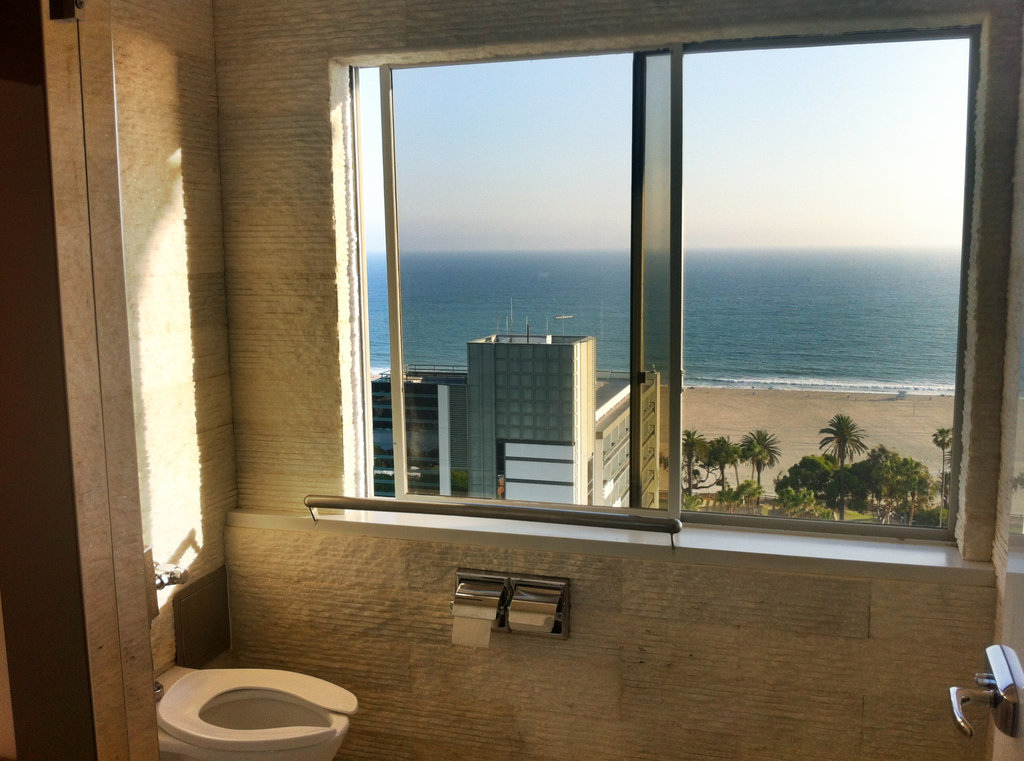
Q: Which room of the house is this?
A: It is a bathroom.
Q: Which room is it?
A: It is a bathroom.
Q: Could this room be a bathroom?
A: Yes, it is a bathroom.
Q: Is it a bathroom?
A: Yes, it is a bathroom.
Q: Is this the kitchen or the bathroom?
A: It is the bathroom.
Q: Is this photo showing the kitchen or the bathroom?
A: It is showing the bathroom.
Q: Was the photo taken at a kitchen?
A: No, the picture was taken in a bathroom.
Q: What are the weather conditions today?
A: It is cloudless.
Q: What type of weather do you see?
A: It is cloudless.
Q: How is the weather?
A: It is cloudless.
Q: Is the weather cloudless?
A: Yes, it is cloudless.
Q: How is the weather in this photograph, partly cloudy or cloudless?
A: It is cloudless.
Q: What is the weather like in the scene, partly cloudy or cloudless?
A: It is cloudless.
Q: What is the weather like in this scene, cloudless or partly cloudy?
A: It is cloudless.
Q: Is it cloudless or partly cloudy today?
A: It is cloudless.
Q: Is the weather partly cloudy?
A: No, it is cloudless.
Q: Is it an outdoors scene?
A: Yes, it is outdoors.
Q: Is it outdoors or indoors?
A: It is outdoors.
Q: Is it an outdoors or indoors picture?
A: It is outdoors.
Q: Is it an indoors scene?
A: No, it is outdoors.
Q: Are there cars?
A: No, there are no cars.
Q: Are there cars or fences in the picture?
A: No, there are no cars or fences.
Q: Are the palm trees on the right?
A: Yes, the palm trees are on the right of the image.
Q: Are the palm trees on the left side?
A: No, the palm trees are on the right of the image.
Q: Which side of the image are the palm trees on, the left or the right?
A: The palm trees are on the right of the image.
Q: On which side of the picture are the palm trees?
A: The palm trees are on the right of the image.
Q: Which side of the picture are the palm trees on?
A: The palm trees are on the right of the image.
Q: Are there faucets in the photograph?
A: No, there are no faucets.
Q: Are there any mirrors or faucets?
A: No, there are no faucets or mirrors.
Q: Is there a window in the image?
A: Yes, there is a window.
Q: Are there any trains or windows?
A: Yes, there is a window.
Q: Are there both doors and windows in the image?
A: Yes, there are both a window and a door.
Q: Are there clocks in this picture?
A: No, there are no clocks.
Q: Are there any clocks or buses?
A: No, there are no clocks or buses.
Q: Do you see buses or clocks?
A: No, there are no clocks or buses.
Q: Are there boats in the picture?
A: No, there are no boats.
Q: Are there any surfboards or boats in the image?
A: No, there are no boats or surfboards.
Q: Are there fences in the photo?
A: No, there are no fences.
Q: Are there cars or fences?
A: No, there are no fences or cars.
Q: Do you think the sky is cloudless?
A: Yes, the sky is cloudless.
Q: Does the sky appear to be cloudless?
A: Yes, the sky is cloudless.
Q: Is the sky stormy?
A: No, the sky is cloudless.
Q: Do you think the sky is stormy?
A: No, the sky is cloudless.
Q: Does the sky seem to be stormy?
A: No, the sky is cloudless.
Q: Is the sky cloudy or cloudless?
A: The sky is cloudless.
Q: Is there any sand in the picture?
A: Yes, there is sand.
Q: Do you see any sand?
A: Yes, there is sand.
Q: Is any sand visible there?
A: Yes, there is sand.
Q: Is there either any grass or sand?
A: Yes, there is sand.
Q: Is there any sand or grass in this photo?
A: Yes, there is sand.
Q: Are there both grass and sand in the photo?
A: No, there is sand but no grass.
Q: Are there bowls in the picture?
A: No, there are no bowls.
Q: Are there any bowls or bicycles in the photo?
A: No, there are no bowls or bicycles.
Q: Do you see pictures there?
A: No, there are no pictures.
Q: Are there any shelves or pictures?
A: No, there are no pictures or shelves.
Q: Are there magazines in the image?
A: No, there are no magazines.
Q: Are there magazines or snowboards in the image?
A: No, there are no magazines or snowboards.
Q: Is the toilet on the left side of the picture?
A: Yes, the toilet is on the left of the image.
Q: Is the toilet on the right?
A: No, the toilet is on the left of the image.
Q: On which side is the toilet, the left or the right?
A: The toilet is on the left of the image.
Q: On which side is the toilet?
A: The toilet is on the left of the image.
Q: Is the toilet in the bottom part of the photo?
A: Yes, the toilet is in the bottom of the image.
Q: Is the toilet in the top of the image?
A: No, the toilet is in the bottom of the image.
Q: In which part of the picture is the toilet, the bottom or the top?
A: The toilet is in the bottom of the image.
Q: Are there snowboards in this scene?
A: No, there are no snowboards.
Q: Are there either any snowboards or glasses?
A: No, there are no snowboards or glasses.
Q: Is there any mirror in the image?
A: No, there are no mirrors.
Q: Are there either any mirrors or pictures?
A: No, there are no mirrors or pictures.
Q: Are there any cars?
A: No, there are no cars.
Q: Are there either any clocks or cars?
A: No, there are no cars or clocks.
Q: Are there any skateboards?
A: No, there are no skateboards.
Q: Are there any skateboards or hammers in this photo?
A: No, there are no skateboards or hammers.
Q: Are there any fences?
A: No, there are no fences.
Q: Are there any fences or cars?
A: No, there are no fences or cars.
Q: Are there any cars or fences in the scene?
A: No, there are no fences or cars.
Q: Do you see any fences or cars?
A: No, there are no fences or cars.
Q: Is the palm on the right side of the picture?
A: Yes, the palm is on the right of the image.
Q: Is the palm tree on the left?
A: No, the palm tree is on the right of the image.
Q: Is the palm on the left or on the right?
A: The palm is on the right of the image.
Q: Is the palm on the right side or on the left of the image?
A: The palm is on the right of the image.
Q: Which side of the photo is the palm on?
A: The palm is on the right of the image.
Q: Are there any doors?
A: Yes, there is a door.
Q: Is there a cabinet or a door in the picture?
A: Yes, there is a door.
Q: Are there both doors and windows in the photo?
A: Yes, there are both a door and windows.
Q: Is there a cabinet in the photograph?
A: No, there are no cabinets.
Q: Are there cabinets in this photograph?
A: No, there are no cabinets.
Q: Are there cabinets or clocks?
A: No, there are no cabinets or clocks.